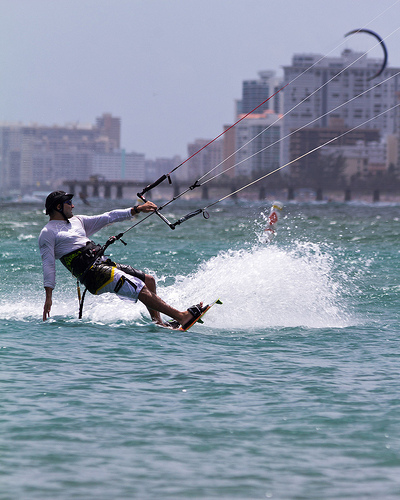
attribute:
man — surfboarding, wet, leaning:
[32, 185, 224, 332]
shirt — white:
[33, 208, 134, 292]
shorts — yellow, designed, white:
[76, 263, 153, 307]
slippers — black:
[159, 294, 212, 335]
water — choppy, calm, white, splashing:
[0, 203, 398, 499]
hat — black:
[40, 190, 78, 219]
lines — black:
[180, 0, 393, 204]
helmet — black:
[38, 187, 70, 212]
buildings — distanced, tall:
[1, 45, 399, 203]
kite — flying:
[334, 20, 385, 89]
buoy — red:
[256, 200, 286, 254]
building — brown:
[288, 127, 380, 177]